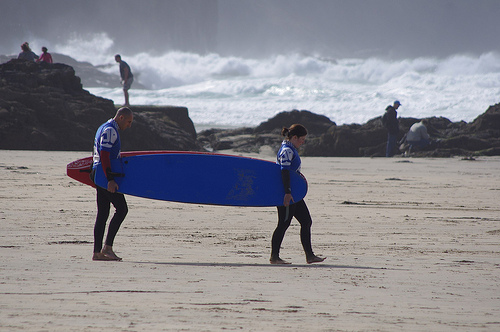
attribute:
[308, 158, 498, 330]
beach — sandy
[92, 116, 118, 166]
tshirt — blue, white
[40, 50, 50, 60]
blouse — pink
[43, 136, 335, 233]
surfboard — blue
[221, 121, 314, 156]
waves — crashing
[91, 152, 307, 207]
surfboard — red, blue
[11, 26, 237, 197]
rock — large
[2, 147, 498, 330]
floor — brown